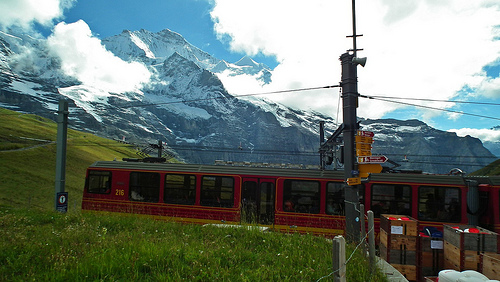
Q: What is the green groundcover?
A: Grass.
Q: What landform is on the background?
A: Mountains.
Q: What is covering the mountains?
A: Snow.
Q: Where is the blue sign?
A: In front of the train.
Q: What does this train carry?
A: Passengers.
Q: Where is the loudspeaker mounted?
A: Pole.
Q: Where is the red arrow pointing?
A: Right.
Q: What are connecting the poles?
A: Cables.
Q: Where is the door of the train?
A: Middle.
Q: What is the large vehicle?
A: Train.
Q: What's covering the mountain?
A: Snow.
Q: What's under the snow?
A: Mountain.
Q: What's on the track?
A: Train.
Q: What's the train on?
A: Track.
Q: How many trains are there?
A: One.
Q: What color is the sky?
A: Blue.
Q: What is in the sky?
A: Clouds.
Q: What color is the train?
A: Red and yellow.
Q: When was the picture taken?
A: Daytime.